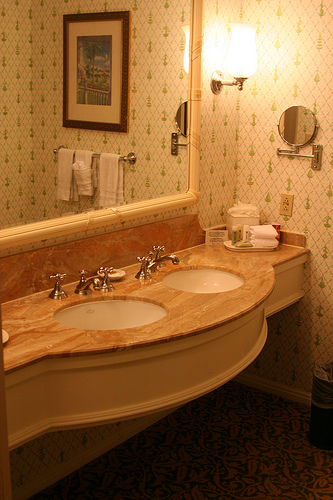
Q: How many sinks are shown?
A: 2.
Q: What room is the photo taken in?
A: Bathroom.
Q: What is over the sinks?
A: Mirror.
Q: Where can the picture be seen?
A: Reflection in the mirror.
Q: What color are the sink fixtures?
A: Silver.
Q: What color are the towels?
A: White.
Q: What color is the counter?
A: Brown.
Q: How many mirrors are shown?
A: 2.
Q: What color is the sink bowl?
A: White.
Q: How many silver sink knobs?
A: Four.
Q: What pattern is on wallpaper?
A: Diamond.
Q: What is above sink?
A: White framed mirror.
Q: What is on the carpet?
A: Leaves pattern.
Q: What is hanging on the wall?
A: Framed picture.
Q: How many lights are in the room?
A: One.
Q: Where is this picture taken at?
A: Bathroom.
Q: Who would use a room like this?
A: People.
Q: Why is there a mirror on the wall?
A: To see.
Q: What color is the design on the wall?
A: Green.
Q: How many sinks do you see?
A: Two.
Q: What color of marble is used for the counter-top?
A: Brown.